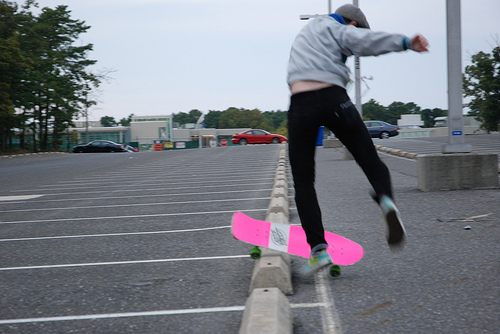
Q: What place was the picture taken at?
A: It was taken at the parking lot.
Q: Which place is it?
A: It is a parking lot.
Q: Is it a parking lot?
A: Yes, it is a parking lot.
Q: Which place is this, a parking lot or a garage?
A: It is a parking lot.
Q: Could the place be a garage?
A: No, it is a parking lot.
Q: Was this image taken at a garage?
A: No, the picture was taken in a parking lot.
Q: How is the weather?
A: It is overcast.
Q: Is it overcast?
A: Yes, it is overcast.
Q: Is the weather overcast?
A: Yes, it is overcast.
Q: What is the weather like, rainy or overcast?
A: It is overcast.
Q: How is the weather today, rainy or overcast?
A: It is overcast.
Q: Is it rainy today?
A: No, it is overcast.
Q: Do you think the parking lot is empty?
A: Yes, the parking lot is empty.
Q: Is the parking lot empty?
A: Yes, the parking lot is empty.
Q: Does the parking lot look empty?
A: Yes, the parking lot is empty.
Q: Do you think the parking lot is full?
A: No, the parking lot is empty.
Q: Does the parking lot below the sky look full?
A: No, the parking lot is empty.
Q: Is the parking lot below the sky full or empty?
A: The parking lot is empty.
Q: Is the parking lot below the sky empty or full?
A: The parking lot is empty.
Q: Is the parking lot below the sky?
A: Yes, the parking lot is below the sky.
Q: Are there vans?
A: No, there are no vans.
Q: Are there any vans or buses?
A: No, there are no vans or buses.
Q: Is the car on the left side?
A: Yes, the car is on the left of the image.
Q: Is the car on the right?
A: No, the car is on the left of the image.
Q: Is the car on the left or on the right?
A: The car is on the left of the image.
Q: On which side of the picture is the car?
A: The car is on the left of the image.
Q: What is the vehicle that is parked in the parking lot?
A: The vehicle is a car.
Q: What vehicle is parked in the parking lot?
A: The vehicle is a car.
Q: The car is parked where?
A: The car is parked in the parking lot.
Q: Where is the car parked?
A: The car is parked in the parking lot.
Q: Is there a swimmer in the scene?
A: No, there are no swimmers.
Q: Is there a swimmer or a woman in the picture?
A: No, there are no swimmers or women.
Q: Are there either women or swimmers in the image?
A: No, there are no swimmers or women.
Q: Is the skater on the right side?
A: Yes, the skater is on the right of the image.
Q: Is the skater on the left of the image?
A: No, the skater is on the right of the image.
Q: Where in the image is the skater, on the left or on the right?
A: The skater is on the right of the image.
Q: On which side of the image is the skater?
A: The skater is on the right of the image.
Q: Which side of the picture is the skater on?
A: The skater is on the right of the image.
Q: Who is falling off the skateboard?
A: The skater is falling off the skateboard.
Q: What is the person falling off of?
A: The skater is falling off the skateboard.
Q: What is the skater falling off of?
A: The skater is falling off the skateboard.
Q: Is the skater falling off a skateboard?
A: Yes, the skater is falling off a skateboard.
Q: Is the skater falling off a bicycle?
A: No, the skater is falling off a skateboard.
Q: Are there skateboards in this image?
A: Yes, there is a skateboard.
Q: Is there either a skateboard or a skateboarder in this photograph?
A: Yes, there is a skateboard.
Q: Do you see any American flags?
A: No, there are no American flags.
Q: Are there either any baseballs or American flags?
A: No, there are no American flags or baseballs.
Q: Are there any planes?
A: No, there are no planes.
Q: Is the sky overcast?
A: Yes, the sky is overcast.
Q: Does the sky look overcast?
A: Yes, the sky is overcast.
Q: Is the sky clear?
A: No, the sky is overcast.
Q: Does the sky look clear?
A: No, the sky is overcast.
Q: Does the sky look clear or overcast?
A: The sky is overcast.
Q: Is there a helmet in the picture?
A: No, there are no helmets.